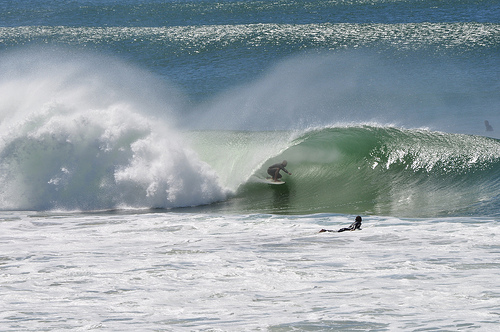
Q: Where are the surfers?
A: In the room.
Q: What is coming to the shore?
A: The wave.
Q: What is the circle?
A: Green.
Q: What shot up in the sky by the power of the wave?
A: The water droplets.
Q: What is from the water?
A: The spray.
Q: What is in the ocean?
A: The giant wave.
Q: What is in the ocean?
A: Two surfers.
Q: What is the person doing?
A: Surfing.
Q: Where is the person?
A: Ocean.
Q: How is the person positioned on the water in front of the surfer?
A: Lying down.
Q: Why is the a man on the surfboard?
A: To surf.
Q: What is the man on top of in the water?
A: Surfboard.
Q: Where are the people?
A: Beach.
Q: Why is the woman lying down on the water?
A: To enjoy the splash from the wave.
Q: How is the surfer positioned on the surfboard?
A: Squatting.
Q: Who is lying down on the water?
A: Male surfer.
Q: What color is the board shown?
A: White.